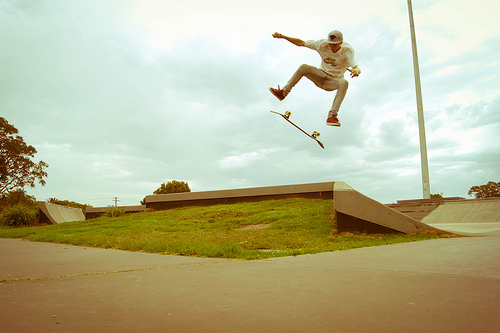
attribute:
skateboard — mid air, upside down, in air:
[270, 106, 325, 150]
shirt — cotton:
[303, 41, 358, 78]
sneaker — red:
[272, 87, 284, 102]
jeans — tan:
[283, 63, 349, 116]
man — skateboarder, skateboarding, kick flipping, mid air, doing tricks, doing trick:
[272, 30, 364, 131]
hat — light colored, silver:
[324, 29, 344, 48]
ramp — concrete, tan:
[328, 182, 469, 237]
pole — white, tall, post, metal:
[408, 1, 435, 201]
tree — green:
[3, 117, 51, 204]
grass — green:
[11, 201, 452, 256]